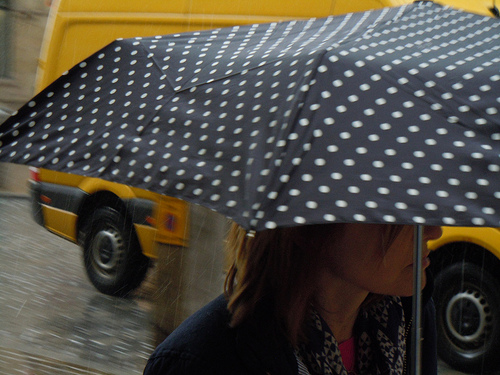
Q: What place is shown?
A: It is a street.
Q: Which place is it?
A: It is a street.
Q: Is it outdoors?
A: Yes, it is outdoors.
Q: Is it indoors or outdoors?
A: It is outdoors.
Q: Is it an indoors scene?
A: No, it is outdoors.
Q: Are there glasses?
A: No, there are no glasses.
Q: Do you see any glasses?
A: No, there are no glasses.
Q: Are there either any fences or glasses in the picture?
A: No, there are no glasses or fences.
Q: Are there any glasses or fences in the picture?
A: No, there are no glasses or fences.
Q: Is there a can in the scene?
A: No, there are no cans.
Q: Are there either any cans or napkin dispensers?
A: No, there are no cans or napkin dispensers.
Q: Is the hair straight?
A: Yes, the hair is straight.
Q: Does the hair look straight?
A: Yes, the hair is straight.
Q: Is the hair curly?
A: No, the hair is straight.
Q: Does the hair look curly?
A: No, the hair is straight.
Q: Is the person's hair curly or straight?
A: The hair is straight.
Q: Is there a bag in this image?
A: No, there are no bags.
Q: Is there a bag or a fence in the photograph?
A: No, there are no bags or fences.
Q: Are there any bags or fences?
A: No, there are no bags or fences.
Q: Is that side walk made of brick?
A: Yes, the side walk is made of brick.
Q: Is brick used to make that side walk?
A: Yes, the side walk is made of brick.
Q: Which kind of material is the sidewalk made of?
A: The sidewalk is made of brick.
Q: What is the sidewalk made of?
A: The sidewalk is made of brick.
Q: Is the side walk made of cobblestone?
A: No, the side walk is made of brick.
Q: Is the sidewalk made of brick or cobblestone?
A: The sidewalk is made of brick.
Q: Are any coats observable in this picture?
A: Yes, there is a coat.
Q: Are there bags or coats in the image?
A: Yes, there is a coat.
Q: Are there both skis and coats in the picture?
A: No, there is a coat but no skis.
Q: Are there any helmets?
A: No, there are no helmets.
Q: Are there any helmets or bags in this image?
A: No, there are no helmets or bags.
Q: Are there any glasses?
A: No, there are no glasses.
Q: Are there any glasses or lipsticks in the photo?
A: No, there are no glasses or lipsticks.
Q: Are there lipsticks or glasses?
A: No, there are no glasses or lipsticks.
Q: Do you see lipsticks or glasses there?
A: No, there are no glasses or lipsticks.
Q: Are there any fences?
A: No, there are no fences.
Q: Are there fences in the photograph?
A: No, there are no fences.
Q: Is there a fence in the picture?
A: No, there are no fences.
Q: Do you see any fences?
A: No, there are no fences.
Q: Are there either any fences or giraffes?
A: No, there are no fences or giraffes.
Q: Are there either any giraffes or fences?
A: No, there are no fences or giraffes.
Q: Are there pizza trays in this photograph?
A: No, there are no pizza trays.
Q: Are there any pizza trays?
A: No, there are no pizza trays.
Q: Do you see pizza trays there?
A: No, there are no pizza trays.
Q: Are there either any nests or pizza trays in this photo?
A: No, there are no pizza trays or nests.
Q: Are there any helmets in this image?
A: No, there are no helmets.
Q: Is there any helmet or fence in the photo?
A: No, there are no helmets or fences.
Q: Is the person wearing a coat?
A: Yes, the person is wearing a coat.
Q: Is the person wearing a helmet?
A: No, the person is wearing a coat.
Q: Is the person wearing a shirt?
A: Yes, the person is wearing a shirt.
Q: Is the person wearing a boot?
A: No, the person is wearing a shirt.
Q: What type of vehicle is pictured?
A: The vehicle is a car.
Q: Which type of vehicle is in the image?
A: The vehicle is a car.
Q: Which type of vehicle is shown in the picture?
A: The vehicle is a car.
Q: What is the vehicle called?
A: The vehicle is a car.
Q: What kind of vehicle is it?
A: The vehicle is a car.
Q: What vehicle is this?
A: This is a car.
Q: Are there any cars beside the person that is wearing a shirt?
A: Yes, there is a car beside the person.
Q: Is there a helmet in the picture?
A: No, there are no helmets.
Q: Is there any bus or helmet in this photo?
A: No, there are no helmets or buses.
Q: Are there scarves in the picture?
A: Yes, there is a scarf.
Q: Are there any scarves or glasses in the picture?
A: Yes, there is a scarf.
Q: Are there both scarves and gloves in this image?
A: No, there is a scarf but no gloves.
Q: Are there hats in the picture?
A: No, there are no hats.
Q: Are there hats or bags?
A: No, there are no hats or bags.